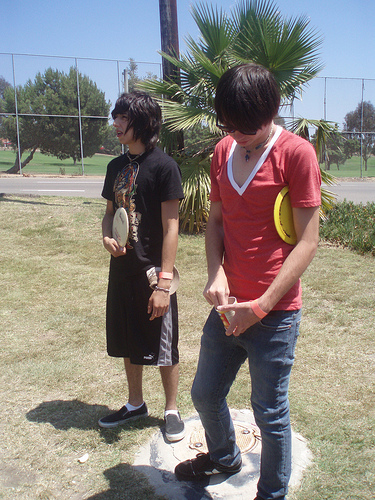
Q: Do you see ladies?
A: No, there are no ladies.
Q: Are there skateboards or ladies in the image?
A: No, there are no ladies or skateboards.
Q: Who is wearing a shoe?
A: The boys are wearing a shoe.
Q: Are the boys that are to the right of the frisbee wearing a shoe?
A: Yes, the boys are wearing a shoe.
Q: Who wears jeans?
A: The boys wear jeans.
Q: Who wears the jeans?
A: The boys wear jeans.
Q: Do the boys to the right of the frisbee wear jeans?
A: Yes, the boys wear jeans.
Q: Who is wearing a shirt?
A: The boys are wearing a shirt.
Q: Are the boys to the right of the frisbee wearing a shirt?
A: Yes, the boys are wearing a shirt.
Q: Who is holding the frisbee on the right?
A: The boys are holding the frisbee.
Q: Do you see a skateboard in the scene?
A: No, there are no skateboards.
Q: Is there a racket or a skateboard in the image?
A: No, there are no skateboards or rackets.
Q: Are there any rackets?
A: No, there are no rackets.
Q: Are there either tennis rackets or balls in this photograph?
A: No, there are no tennis rackets or balls.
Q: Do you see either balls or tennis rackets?
A: No, there are no tennis rackets or balls.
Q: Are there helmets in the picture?
A: No, there are no helmets.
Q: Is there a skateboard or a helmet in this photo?
A: No, there are no helmets or skateboards.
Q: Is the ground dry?
A: Yes, the ground is dry.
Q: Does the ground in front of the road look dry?
A: Yes, the ground is dry.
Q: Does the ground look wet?
A: No, the ground is dry.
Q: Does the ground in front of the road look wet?
A: No, the ground is dry.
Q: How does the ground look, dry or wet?
A: The ground is dry.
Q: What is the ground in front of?
A: The ground is in front of the road.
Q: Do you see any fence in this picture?
A: Yes, there is a fence.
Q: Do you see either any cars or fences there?
A: Yes, there is a fence.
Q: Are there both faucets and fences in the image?
A: No, there is a fence but no faucets.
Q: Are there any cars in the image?
A: No, there are no cars.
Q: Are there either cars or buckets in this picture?
A: No, there are no cars or buckets.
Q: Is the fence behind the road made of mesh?
A: Yes, the fence is made of mesh.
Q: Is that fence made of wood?
A: No, the fence is made of mesh.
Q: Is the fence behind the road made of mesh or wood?
A: The fence is made of mesh.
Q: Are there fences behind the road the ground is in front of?
A: Yes, there is a fence behind the road.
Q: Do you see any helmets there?
A: No, there are no helmets.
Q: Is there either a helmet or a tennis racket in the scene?
A: No, there are no helmets or rackets.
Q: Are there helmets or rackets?
A: No, there are no helmets or rackets.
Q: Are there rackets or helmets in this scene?
A: No, there are no helmets or rackets.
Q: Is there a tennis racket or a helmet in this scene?
A: No, there are no helmets or rackets.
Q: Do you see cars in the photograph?
A: No, there are no cars.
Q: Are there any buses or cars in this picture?
A: No, there are no cars or buses.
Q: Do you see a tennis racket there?
A: No, there are no rackets.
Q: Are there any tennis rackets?
A: No, there are no tennis rackets.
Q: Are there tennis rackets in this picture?
A: No, there are no tennis rackets.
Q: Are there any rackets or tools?
A: No, there are no rackets or tools.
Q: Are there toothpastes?
A: No, there are no toothpastes.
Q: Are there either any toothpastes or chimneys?
A: No, there are no toothpastes or chimneys.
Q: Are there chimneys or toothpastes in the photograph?
A: No, there are no toothpastes or chimneys.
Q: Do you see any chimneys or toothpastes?
A: No, there are no toothpastes or chimneys.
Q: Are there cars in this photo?
A: No, there are no cars.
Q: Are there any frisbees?
A: Yes, there is a frisbee.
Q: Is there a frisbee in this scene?
A: Yes, there is a frisbee.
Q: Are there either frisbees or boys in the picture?
A: Yes, there is a frisbee.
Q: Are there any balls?
A: No, there are no balls.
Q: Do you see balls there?
A: No, there are no balls.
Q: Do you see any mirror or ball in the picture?
A: No, there are no balls or mirrors.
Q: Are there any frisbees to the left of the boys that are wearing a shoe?
A: Yes, there is a frisbee to the left of the boys.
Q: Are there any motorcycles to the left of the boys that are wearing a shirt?
A: No, there is a frisbee to the left of the boys.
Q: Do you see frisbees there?
A: Yes, there is a frisbee.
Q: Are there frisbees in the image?
A: Yes, there is a frisbee.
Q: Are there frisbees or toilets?
A: Yes, there is a frisbee.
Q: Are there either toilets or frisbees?
A: Yes, there is a frisbee.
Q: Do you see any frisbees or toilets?
A: Yes, there is a frisbee.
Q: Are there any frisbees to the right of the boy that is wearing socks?
A: Yes, there is a frisbee to the right of the boy.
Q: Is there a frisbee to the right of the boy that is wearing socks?
A: Yes, there is a frisbee to the right of the boy.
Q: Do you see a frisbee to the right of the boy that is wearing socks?
A: Yes, there is a frisbee to the right of the boy.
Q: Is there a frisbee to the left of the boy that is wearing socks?
A: No, the frisbee is to the right of the boy.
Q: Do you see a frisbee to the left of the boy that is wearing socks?
A: No, the frisbee is to the right of the boy.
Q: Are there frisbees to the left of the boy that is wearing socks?
A: No, the frisbee is to the right of the boy.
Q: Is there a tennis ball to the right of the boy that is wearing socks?
A: No, there is a frisbee to the right of the boy.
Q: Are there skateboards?
A: No, there are no skateboards.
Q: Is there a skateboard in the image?
A: No, there are no skateboards.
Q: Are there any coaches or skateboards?
A: No, there are no skateboards or coaches.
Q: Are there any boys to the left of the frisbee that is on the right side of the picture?
A: Yes, there is a boy to the left of the frisbee.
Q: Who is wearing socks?
A: The boy is wearing socks.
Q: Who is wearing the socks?
A: The boy is wearing socks.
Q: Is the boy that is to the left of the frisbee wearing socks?
A: Yes, the boy is wearing socks.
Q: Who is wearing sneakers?
A: The boy is wearing sneakers.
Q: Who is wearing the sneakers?
A: The boy is wearing sneakers.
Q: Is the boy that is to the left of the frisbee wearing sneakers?
A: Yes, the boy is wearing sneakers.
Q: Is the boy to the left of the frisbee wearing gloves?
A: No, the boy is wearing sneakers.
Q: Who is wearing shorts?
A: The boy is wearing shorts.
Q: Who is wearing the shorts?
A: The boy is wearing shorts.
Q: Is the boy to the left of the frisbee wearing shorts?
A: Yes, the boy is wearing shorts.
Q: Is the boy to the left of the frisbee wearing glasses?
A: No, the boy is wearing shorts.